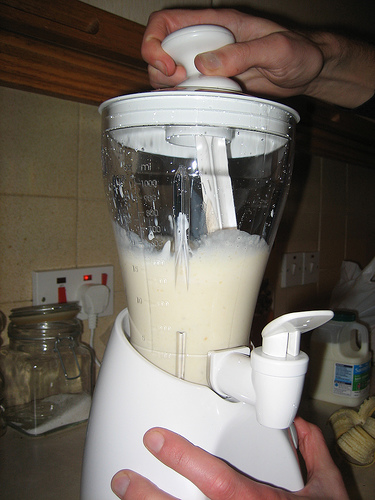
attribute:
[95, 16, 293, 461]
blender — white, glass, plastic, mixing, juicing, small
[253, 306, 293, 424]
spout — white, plastic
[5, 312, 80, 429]
sugar — pile, open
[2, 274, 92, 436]
canister — glass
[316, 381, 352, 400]
milk — white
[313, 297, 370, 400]
jug — plastic, milk, gallon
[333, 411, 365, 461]
banana peel — yellow, curled up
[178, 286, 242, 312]
liquid — white, being stirred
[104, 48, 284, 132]
top — white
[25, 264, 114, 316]
wall outlet — electric, white, electrical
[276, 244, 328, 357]
wall switches — electric, white, plastic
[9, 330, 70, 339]
container — glass, open, clear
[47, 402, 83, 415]
powder — white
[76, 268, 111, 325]
socket — lighted, white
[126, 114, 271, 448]
juicier — large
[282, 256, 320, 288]
light switches — white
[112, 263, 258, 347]
fruit juice — blended, white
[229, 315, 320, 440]
nozzle — pouring, white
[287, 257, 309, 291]
outlet — electrical, white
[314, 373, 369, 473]
banana peels — bunch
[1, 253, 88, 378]
jar — glass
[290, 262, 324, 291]
switches — white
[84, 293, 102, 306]
plug — white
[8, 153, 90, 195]
tile — beige